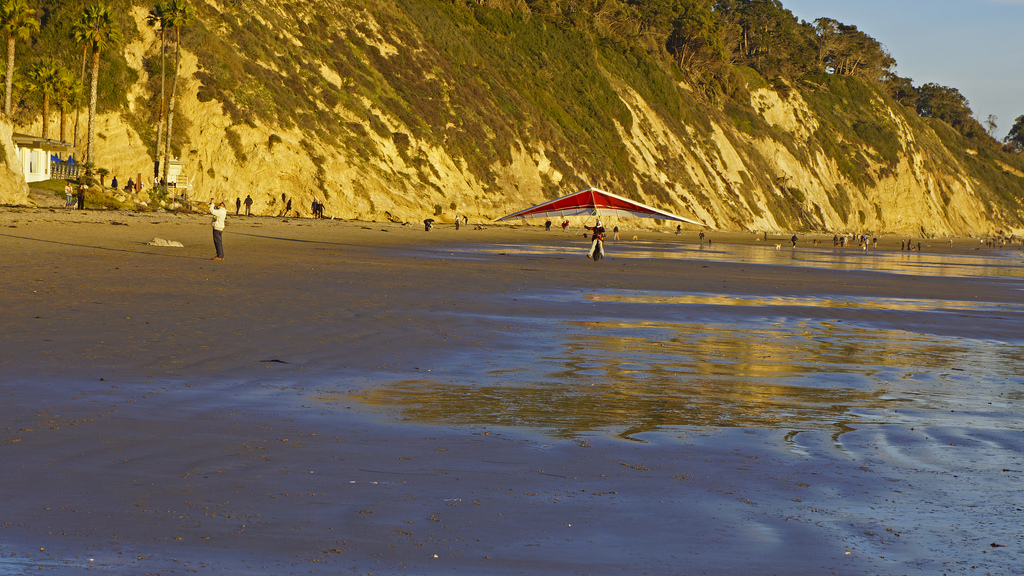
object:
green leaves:
[717, 2, 786, 43]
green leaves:
[807, 15, 861, 59]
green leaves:
[739, 1, 786, 30]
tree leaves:
[677, 1, 749, 61]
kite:
[495, 187, 716, 236]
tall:
[147, 96, 175, 208]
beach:
[46, 220, 300, 331]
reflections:
[607, 300, 857, 417]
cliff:
[0, 0, 1022, 230]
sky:
[871, 0, 1024, 98]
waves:
[710, 425, 1024, 465]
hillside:
[0, 0, 1024, 240]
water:
[0, 274, 1022, 574]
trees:
[807, 14, 972, 133]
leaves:
[750, 14, 900, 73]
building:
[9, 131, 83, 183]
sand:
[0, 222, 443, 262]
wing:
[528, 186, 652, 215]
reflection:
[444, 243, 1024, 278]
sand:
[566, 226, 995, 258]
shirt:
[208, 204, 227, 232]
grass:
[373, 43, 616, 150]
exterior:
[0, 210, 88, 286]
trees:
[480, 0, 1020, 147]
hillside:
[262, 203, 720, 258]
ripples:
[542, 380, 1022, 441]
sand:
[436, 367, 1024, 576]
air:
[88, 220, 132, 249]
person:
[581, 216, 608, 263]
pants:
[588, 239, 607, 256]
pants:
[213, 229, 226, 259]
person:
[206, 197, 226, 262]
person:
[788, 234, 797, 249]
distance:
[389, 241, 1022, 468]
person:
[205, 197, 232, 262]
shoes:
[210, 255, 226, 261]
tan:
[774, 243, 782, 250]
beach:
[384, 218, 1024, 293]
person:
[424, 218, 437, 233]